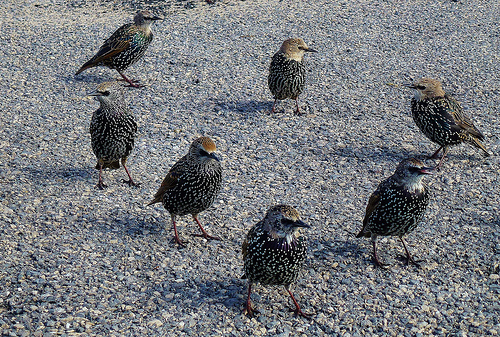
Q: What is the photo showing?
A: It is showing a pavement.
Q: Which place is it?
A: It is a pavement.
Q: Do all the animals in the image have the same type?
A: Yes, all the animals are birds.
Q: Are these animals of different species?
A: No, all the animals are birds.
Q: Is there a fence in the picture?
A: No, there are no fences.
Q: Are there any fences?
A: No, there are no fences.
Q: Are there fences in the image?
A: No, there are no fences.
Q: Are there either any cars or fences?
A: No, there are no fences or cars.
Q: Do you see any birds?
A: Yes, there is a bird.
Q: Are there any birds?
A: Yes, there is a bird.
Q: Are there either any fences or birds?
A: Yes, there is a bird.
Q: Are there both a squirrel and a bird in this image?
A: No, there is a bird but no squirrels.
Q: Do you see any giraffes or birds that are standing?
A: Yes, the bird is standing.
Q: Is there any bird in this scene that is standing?
A: Yes, there is a bird that is standing.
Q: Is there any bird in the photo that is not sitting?
A: Yes, there is a bird that is standing.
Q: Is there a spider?
A: No, there are no spiders.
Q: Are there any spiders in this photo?
A: No, there are no spiders.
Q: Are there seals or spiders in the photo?
A: No, there are no spiders or seals.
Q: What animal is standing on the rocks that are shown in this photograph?
A: The bird is standing on the rocks.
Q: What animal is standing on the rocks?
A: The bird is standing on the rocks.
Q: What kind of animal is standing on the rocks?
A: The animal is a bird.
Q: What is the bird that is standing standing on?
A: The bird is standing on the rocks.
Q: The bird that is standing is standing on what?
A: The bird is standing on the rocks.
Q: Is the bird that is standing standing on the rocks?
A: Yes, the bird is standing on the rocks.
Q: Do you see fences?
A: No, there are no fences.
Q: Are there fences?
A: No, there are no fences.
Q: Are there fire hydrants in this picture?
A: No, there are no fire hydrants.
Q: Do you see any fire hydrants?
A: No, there are no fire hydrants.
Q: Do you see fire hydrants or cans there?
A: No, there are no fire hydrants or cans.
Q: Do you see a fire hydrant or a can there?
A: No, there are no fire hydrants or cans.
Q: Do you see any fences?
A: No, there are no fences.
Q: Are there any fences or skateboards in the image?
A: No, there are no fences or skateboards.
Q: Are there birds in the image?
A: Yes, there is a bird.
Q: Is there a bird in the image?
A: Yes, there is a bird.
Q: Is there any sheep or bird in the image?
A: Yes, there is a bird.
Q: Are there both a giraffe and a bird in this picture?
A: No, there is a bird but no giraffes.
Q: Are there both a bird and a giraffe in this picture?
A: No, there is a bird but no giraffes.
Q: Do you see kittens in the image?
A: No, there are no kittens.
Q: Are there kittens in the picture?
A: No, there are no kittens.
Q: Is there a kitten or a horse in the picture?
A: No, there are no kittens or horses.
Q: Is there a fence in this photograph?
A: No, there are no fences.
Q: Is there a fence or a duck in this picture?
A: No, there are no fences or ducks.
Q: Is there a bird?
A: Yes, there is a bird.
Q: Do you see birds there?
A: Yes, there is a bird.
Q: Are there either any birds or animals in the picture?
A: Yes, there is a bird.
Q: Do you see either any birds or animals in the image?
A: Yes, there is a bird.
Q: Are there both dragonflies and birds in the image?
A: No, there is a bird but no dragonflies.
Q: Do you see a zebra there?
A: No, there are no zebras.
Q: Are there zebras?
A: No, there are no zebras.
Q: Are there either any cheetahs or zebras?
A: No, there are no zebras or cheetahs.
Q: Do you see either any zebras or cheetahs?
A: No, there are no zebras or cheetahs.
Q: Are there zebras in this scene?
A: No, there are no zebras.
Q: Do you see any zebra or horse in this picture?
A: No, there are no zebras or horses.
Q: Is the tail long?
A: Yes, the tail is long.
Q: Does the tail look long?
A: Yes, the tail is long.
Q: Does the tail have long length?
A: Yes, the tail is long.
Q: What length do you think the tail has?
A: The tail has long length.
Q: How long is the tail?
A: The tail is long.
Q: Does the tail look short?
A: No, the tail is long.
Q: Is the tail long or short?
A: The tail is long.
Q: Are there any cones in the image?
A: No, there are no cones.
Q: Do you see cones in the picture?
A: No, there are no cones.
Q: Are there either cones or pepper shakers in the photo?
A: No, there are no cones or pepper shakers.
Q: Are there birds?
A: Yes, there is a bird.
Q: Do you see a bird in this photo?
A: Yes, there is a bird.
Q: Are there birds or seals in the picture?
A: Yes, there is a bird.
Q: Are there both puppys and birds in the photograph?
A: No, there is a bird but no puppys.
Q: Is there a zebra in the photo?
A: No, there are no zebras.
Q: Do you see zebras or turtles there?
A: No, there are no zebras or turtles.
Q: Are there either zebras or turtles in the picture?
A: No, there are no zebras or turtles.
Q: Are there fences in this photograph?
A: No, there are no fences.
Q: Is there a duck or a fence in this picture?
A: No, there are no fences or ducks.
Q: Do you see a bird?
A: Yes, there is a bird.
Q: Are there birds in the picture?
A: Yes, there is a bird.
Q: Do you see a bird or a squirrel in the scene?
A: Yes, there is a bird.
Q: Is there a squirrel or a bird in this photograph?
A: Yes, there is a bird.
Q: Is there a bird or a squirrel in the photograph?
A: Yes, there is a bird.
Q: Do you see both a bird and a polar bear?
A: No, there is a bird but no polar bears.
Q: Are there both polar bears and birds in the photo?
A: No, there is a bird but no polar bears.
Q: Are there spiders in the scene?
A: No, there are no spiders.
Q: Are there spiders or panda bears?
A: No, there are no spiders or panda bears.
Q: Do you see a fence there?
A: No, there are no fences.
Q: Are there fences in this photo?
A: No, there are no fences.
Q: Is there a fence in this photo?
A: No, there are no fences.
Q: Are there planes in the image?
A: No, there are no planes.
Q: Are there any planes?
A: No, there are no planes.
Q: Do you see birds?
A: Yes, there is a bird.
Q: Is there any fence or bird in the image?
A: Yes, there is a bird.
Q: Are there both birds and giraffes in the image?
A: No, there is a bird but no giraffes.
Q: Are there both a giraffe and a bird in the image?
A: No, there is a bird but no giraffes.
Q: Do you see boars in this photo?
A: No, there are no boars.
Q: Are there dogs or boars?
A: No, there are no boars or dogs.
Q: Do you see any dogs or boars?
A: No, there are no boars or dogs.